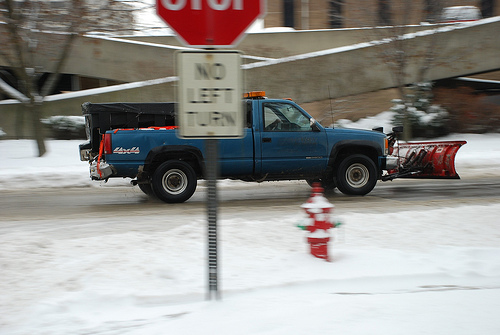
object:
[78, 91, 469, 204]
truck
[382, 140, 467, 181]
plow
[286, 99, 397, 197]
front of truck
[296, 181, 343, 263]
hydrant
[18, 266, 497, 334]
sidewalk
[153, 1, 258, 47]
sign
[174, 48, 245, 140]
traffic sign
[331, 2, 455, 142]
trees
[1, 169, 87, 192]
far sidewalk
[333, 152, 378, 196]
tire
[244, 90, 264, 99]
orange lights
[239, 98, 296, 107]
truck roof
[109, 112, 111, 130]
black straps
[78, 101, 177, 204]
back of truck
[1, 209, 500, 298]
packed snow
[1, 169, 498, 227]
street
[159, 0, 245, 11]
stop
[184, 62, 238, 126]
no left turn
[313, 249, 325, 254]
red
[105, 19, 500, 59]
ramps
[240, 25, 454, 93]
cement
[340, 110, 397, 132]
snow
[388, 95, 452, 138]
bushes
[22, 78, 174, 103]
snow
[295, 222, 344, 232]
green plugs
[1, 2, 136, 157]
tree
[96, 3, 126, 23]
no leaves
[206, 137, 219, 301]
post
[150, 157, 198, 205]
tires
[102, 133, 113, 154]
tail light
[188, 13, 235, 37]
red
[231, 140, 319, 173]
blue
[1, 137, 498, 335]
snow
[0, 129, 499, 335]
ground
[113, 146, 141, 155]
4x4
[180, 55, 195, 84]
white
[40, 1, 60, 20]
brown leaves